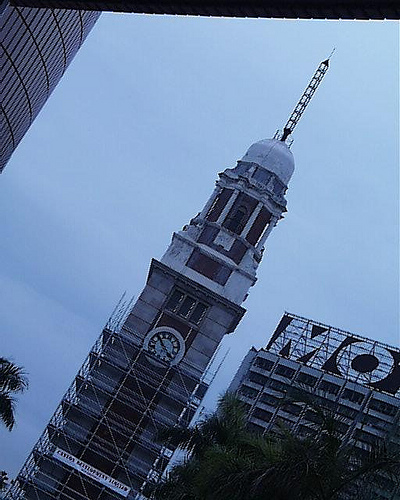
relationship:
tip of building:
[283, 44, 336, 139] [1, 139, 295, 499]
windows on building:
[164, 287, 211, 330] [1, 139, 295, 499]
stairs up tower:
[14, 325, 208, 499] [1, 139, 295, 499]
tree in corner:
[147, 381, 399, 500] [363, 464, 399, 500]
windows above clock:
[164, 287, 211, 330] [143, 326, 186, 368]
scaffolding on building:
[14, 325, 208, 499] [1, 139, 295, 499]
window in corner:
[252, 355, 275, 374] [251, 348, 278, 377]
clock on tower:
[143, 326, 186, 368] [1, 139, 295, 499]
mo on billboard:
[271, 313, 395, 386] [266, 311, 400, 398]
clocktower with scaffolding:
[1, 139, 295, 499] [14, 325, 208, 499]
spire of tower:
[283, 44, 336, 139] [1, 139, 295, 499]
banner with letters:
[53, 446, 131, 498] [56, 449, 129, 490]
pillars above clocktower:
[199, 185, 278, 254] [1, 256, 247, 499]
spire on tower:
[283, 44, 336, 139] [1, 139, 295, 499]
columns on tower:
[199, 185, 278, 254] [1, 139, 295, 499]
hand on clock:
[157, 336, 167, 352] [143, 326, 186, 368]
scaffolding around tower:
[14, 325, 208, 499] [1, 139, 295, 499]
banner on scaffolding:
[53, 446, 131, 498] [14, 325, 208, 499]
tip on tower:
[283, 44, 336, 139] [1, 139, 295, 499]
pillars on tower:
[199, 185, 278, 254] [1, 139, 295, 499]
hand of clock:
[157, 336, 167, 352] [143, 326, 186, 368]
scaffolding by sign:
[14, 325, 208, 499] [53, 446, 131, 498]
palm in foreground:
[147, 381, 399, 500] [1, 399, 399, 498]